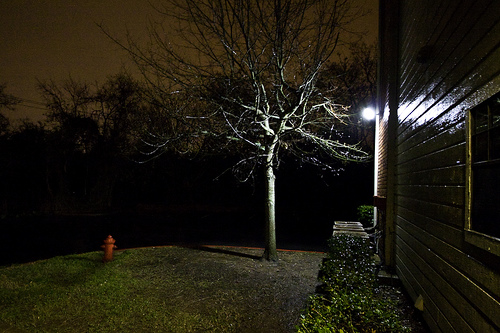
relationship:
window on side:
[465, 92, 499, 239] [373, 0, 493, 331]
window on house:
[465, 92, 499, 239] [369, 0, 498, 331]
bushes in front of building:
[299, 221, 414, 333] [354, 7, 494, 329]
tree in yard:
[111, 17, 371, 260] [2, 232, 342, 331]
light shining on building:
[361, 105, 378, 122] [371, 0, 500, 333]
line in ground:
[287, 237, 328, 267] [109, 247, 256, 314]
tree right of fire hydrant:
[111, 17, 371, 260] [100, 235, 117, 263]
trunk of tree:
[260, 158, 281, 264] [89, 0, 373, 267]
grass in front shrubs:
[1, 243, 303, 329] [296, 234, 415, 330]